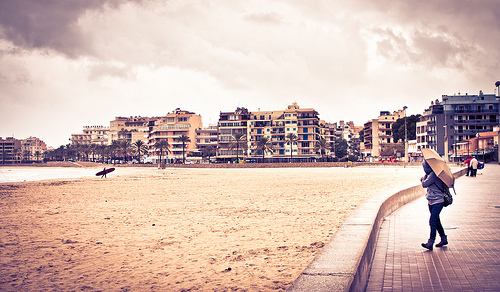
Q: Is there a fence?
A: No, there are no fences.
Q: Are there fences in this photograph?
A: No, there are no fences.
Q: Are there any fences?
A: No, there are no fences.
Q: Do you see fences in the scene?
A: No, there are no fences.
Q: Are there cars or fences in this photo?
A: No, there are no fences or cars.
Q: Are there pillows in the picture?
A: No, there are no pillows.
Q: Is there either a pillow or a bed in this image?
A: No, there are no pillows or beds.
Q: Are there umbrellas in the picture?
A: Yes, there is an umbrella.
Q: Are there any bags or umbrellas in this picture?
A: Yes, there is an umbrella.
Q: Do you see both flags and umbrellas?
A: No, there is an umbrella but no flags.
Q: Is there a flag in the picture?
A: No, there are no flags.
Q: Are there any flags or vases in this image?
A: No, there are no flags or vases.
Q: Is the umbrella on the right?
A: Yes, the umbrella is on the right of the image.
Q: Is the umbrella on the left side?
A: No, the umbrella is on the right of the image.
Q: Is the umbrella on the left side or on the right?
A: The umbrella is on the right of the image.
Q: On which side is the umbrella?
A: The umbrella is on the right of the image.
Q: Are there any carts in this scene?
A: No, there are no carts.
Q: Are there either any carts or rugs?
A: No, there are no carts or rugs.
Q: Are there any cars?
A: No, there are no cars.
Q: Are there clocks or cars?
A: No, there are no cars or clocks.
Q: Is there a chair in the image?
A: No, there are no chairs.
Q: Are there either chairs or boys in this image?
A: No, there are no chairs or boys.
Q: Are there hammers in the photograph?
A: No, there are no hammers.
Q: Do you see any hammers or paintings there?
A: No, there are no hammers or paintings.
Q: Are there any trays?
A: No, there are no trays.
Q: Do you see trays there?
A: No, there are no trays.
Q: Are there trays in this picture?
A: No, there are no trays.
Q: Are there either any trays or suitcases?
A: No, there are no trays or suitcases.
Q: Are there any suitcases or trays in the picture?
A: No, there are no trays or suitcases.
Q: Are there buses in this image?
A: No, there are no buses.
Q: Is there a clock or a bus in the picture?
A: No, there are no buses or clocks.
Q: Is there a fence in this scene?
A: No, there are no fences.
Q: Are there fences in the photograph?
A: No, there are no fences.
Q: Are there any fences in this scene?
A: No, there are no fences.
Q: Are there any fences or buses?
A: No, there are no fences or buses.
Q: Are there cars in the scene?
A: No, there are no cars.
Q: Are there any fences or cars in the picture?
A: No, there are no cars or fences.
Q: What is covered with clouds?
A: The sky is covered with clouds.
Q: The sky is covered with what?
A: The sky is covered with clouds.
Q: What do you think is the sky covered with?
A: The sky is covered with clouds.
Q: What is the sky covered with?
A: The sky is covered with clouds.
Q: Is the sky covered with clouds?
A: Yes, the sky is covered with clouds.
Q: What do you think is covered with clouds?
A: The sky is covered with clouds.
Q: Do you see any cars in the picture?
A: No, there are no cars.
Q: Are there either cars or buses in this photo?
A: No, there are no cars or buses.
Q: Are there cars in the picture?
A: No, there are no cars.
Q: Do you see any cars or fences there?
A: No, there are no cars or fences.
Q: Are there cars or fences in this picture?
A: No, there are no cars or fences.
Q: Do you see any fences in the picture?
A: No, there are no fences.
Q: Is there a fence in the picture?
A: No, there are no fences.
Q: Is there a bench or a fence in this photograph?
A: No, there are no fences or benches.